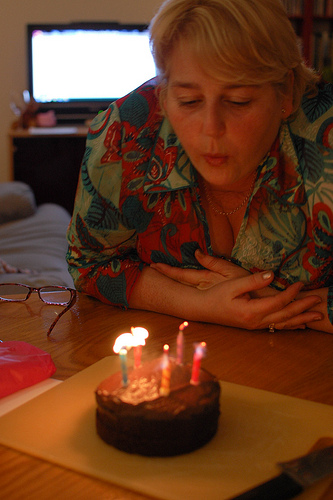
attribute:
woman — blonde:
[73, 8, 327, 274]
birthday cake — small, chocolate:
[94, 355, 220, 456]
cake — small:
[86, 383, 222, 458]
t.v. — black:
[21, 18, 161, 108]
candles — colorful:
[110, 320, 207, 396]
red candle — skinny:
[189, 347, 203, 383]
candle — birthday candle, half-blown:
[187, 341, 205, 385]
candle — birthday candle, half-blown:
[172, 321, 187, 366]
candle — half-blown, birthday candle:
[158, 343, 171, 394]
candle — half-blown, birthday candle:
[128, 325, 149, 370]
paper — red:
[88, 428, 232, 486]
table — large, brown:
[0, 311, 332, 498]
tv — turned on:
[28, 18, 155, 105]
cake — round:
[51, 309, 261, 463]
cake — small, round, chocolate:
[93, 355, 220, 457]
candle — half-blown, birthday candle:
[112, 331, 135, 389]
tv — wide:
[18, 18, 163, 108]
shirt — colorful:
[65, 153, 330, 286]